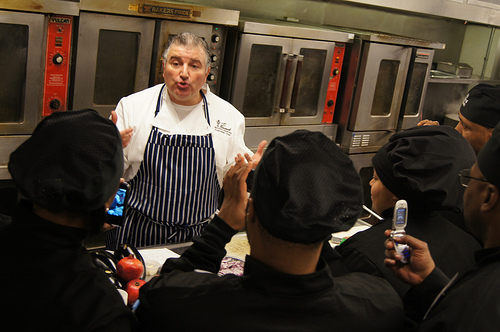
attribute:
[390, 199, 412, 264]
flip phone — silver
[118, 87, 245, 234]
apron — white, black, striped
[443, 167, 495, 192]
glasses — black, metal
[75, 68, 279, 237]
apron — black, white, stripes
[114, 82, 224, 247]
apron — black, white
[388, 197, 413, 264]
cellphone — silver, small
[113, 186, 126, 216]
phone — black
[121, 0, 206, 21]
sign — silver, metal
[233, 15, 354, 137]
oven — metal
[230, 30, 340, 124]
doors — metal, silver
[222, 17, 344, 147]
oven — silver, metal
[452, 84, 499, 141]
person — black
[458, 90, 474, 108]
writing — white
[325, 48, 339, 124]
knobs — black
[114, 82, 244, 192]
shirt — white